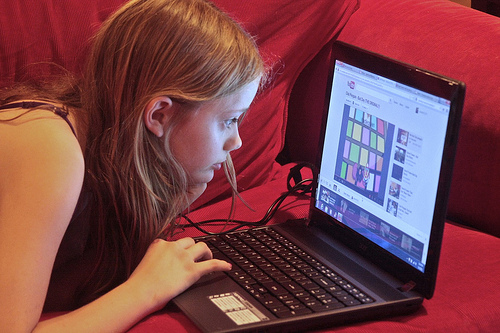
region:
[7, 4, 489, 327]
a little girl in front a laptop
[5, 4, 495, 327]
girl lying on a red couch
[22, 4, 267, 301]
girl has long hair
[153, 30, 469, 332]
laptop is color black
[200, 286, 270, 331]
a label on top of laptop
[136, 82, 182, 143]
right ear of girl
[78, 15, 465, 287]
girl is looking the screen of laptop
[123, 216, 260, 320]
a hand touching a keyboard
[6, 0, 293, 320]
kid wears a tank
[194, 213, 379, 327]
keyboard has white letters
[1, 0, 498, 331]
THE COUCH IS RED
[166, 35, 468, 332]
THE LAPTOP IS BLACK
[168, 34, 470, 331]
THIS IS A LAPTOP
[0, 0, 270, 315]
THE GIRL HAS BROWN HAIR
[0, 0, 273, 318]
THE GIRL HAS LONG HAIR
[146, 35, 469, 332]
THE GIRL IS TOUCHING THE LAPTOP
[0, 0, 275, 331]
THE GIRL IS LOOKING AT THE LAPTOP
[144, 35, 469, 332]
THE LAPTOP IS BRIGHT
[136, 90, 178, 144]
THE GIRL'S EAR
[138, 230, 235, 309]
THE GIRL'S HAND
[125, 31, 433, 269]
girl looking at computer screen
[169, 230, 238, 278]
hand on black laptop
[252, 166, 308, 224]
wires on side of laptop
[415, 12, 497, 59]
arm on side of couch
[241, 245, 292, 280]
buttons on laptop keyboard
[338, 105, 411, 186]
image on computer screen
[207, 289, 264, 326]
label under laptop keyboard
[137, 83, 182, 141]
ear on girl's head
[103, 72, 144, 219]
long light brown hair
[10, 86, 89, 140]
strap on girl's shoulder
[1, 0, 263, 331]
young girl using a computer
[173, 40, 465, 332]
a black laptop computer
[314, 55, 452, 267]
screen of the computer showing YouTube video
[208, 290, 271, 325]
a sticker on the computer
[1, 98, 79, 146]
clothing strap on girl's shoulder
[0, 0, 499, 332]
a red couch under the girl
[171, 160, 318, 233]
black electrical cord of computer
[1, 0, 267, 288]
girl's long, blonde hair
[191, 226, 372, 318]
black keyboard of the computer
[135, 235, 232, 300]
girl's hand on the computer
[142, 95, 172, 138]
a woman's ear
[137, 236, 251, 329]
a woman's hand using a computer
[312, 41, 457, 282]
the screen of a computer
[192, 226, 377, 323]
a laptop computer keyboard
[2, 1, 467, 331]
a young woman using a laptop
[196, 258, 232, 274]
a woman's pinky finger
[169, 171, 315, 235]
cables for a laptop power supply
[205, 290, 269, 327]
sticker on a laptop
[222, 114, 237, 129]
a young woman's eye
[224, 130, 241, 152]
a young woman's nose